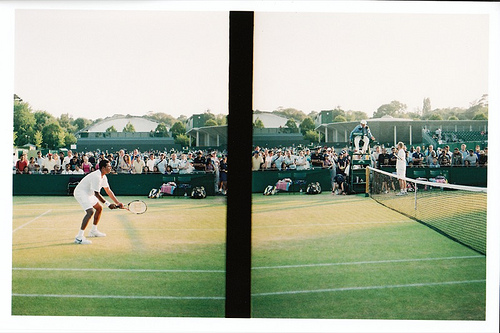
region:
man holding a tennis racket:
[58, 163, 154, 266]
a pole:
[218, 21, 278, 306]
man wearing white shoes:
[76, 225, 101, 252]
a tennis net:
[378, 173, 462, 233]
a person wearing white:
[391, 146, 411, 173]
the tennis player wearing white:
[75, 169, 123, 216]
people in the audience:
[111, 151, 194, 169]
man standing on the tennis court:
[91, 234, 160, 282]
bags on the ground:
[158, 180, 203, 194]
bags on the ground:
[270, 177, 320, 196]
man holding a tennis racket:
[105, 188, 150, 220]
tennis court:
[280, 216, 400, 310]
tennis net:
[387, 180, 477, 238]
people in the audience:
[48, 142, 160, 165]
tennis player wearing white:
[73, 171, 113, 212]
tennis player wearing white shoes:
[76, 231, 91, 247]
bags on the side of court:
[263, 176, 323, 196]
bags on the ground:
[146, 184, 213, 203]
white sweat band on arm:
[100, 200, 116, 210]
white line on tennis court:
[308, 257, 367, 279]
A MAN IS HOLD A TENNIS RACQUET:
[62, 157, 148, 239]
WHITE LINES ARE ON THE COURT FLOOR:
[15, 257, 495, 315]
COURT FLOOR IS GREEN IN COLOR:
[0, 178, 482, 315]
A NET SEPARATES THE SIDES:
[360, 162, 488, 257]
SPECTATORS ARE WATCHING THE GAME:
[14, 149, 481, 180]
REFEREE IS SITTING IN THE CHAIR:
[349, 114, 385, 149]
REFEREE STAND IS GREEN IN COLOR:
[341, 144, 378, 201]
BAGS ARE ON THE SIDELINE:
[147, 174, 215, 196]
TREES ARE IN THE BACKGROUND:
[11, 90, 86, 156]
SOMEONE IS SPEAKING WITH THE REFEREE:
[381, 136, 420, 197]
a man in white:
[85, 148, 202, 290]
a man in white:
[18, 92, 200, 316]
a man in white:
[86, 81, 219, 245]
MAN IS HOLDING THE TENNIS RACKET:
[99, 200, 173, 217]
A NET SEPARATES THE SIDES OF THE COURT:
[357, 152, 498, 259]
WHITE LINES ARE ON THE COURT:
[3, 249, 480, 304]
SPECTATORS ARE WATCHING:
[14, 142, 484, 168]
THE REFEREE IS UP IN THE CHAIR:
[345, 115, 385, 190]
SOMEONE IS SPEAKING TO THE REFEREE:
[387, 136, 412, 206]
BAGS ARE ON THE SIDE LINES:
[142, 177, 214, 202]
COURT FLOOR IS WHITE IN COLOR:
[260, 200, 491, 306]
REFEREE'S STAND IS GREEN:
[346, 140, 386, 200]